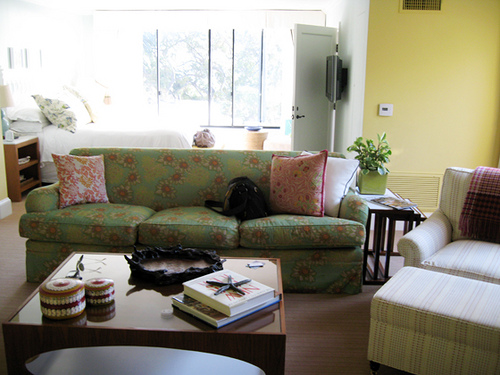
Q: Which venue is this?
A: This is a living room.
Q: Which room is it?
A: It is a living room.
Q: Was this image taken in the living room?
A: Yes, it was taken in the living room.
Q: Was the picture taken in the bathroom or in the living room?
A: It was taken at the living room.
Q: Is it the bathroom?
A: No, it is the living room.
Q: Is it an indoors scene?
A: Yes, it is indoors.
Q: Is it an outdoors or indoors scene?
A: It is indoors.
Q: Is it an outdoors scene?
A: No, it is indoors.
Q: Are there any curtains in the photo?
A: No, there are no curtains.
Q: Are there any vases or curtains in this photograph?
A: No, there are no curtains or vases.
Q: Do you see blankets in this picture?
A: Yes, there is a blanket.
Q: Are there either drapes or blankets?
A: Yes, there is a blanket.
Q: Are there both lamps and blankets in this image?
A: Yes, there are both a blanket and a lamp.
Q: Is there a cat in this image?
A: No, there are no cats.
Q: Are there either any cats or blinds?
A: No, there are no cats or blinds.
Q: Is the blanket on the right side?
A: Yes, the blanket is on the right of the image.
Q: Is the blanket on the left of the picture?
A: No, the blanket is on the right of the image.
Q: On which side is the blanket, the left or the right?
A: The blanket is on the right of the image.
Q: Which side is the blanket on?
A: The blanket is on the right of the image.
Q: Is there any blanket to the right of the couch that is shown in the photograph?
A: Yes, there is a blanket to the right of the couch.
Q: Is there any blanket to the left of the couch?
A: No, the blanket is to the right of the couch.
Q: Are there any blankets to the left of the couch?
A: No, the blanket is to the right of the couch.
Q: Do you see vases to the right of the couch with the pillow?
A: No, there is a blanket to the right of the couch.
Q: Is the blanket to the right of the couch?
A: Yes, the blanket is to the right of the couch.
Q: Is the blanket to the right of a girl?
A: No, the blanket is to the right of the couch.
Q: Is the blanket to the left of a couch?
A: No, the blanket is to the right of a couch.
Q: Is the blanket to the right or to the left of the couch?
A: The blanket is to the right of the couch.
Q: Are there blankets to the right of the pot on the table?
A: Yes, there is a blanket to the right of the pot.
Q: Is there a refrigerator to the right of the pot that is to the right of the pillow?
A: No, there is a blanket to the right of the pot.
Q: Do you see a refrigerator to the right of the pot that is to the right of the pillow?
A: No, there is a blanket to the right of the pot.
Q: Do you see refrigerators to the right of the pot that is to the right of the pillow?
A: No, there is a blanket to the right of the pot.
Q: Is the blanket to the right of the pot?
A: Yes, the blanket is to the right of the pot.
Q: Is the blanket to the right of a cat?
A: No, the blanket is to the right of the pot.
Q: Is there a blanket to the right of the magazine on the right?
A: Yes, there is a blanket to the right of the magazine.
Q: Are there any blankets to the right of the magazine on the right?
A: Yes, there is a blanket to the right of the magazine.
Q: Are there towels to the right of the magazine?
A: No, there is a blanket to the right of the magazine.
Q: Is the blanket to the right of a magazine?
A: Yes, the blanket is to the right of a magazine.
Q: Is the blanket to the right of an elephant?
A: No, the blanket is to the right of a magazine.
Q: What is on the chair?
A: The blanket is on the chair.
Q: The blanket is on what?
A: The blanket is on the chair.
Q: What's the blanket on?
A: The blanket is on the chair.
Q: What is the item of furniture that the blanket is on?
A: The piece of furniture is a chair.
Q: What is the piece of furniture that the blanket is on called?
A: The piece of furniture is a chair.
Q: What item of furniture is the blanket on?
A: The blanket is on the chair.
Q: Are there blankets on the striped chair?
A: Yes, there is a blanket on the chair.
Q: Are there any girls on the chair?
A: No, there is a blanket on the chair.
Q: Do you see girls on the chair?
A: No, there is a blanket on the chair.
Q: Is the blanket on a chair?
A: Yes, the blanket is on a chair.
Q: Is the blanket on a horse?
A: No, the blanket is on a chair.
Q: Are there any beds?
A: Yes, there is a bed.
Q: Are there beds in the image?
A: Yes, there is a bed.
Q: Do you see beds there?
A: Yes, there is a bed.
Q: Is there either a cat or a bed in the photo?
A: Yes, there is a bed.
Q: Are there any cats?
A: No, there are no cats.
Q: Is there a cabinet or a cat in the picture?
A: No, there are no cats or cabinets.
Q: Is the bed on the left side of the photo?
A: Yes, the bed is on the left of the image.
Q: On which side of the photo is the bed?
A: The bed is on the left of the image.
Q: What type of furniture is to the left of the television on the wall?
A: The piece of furniture is a bed.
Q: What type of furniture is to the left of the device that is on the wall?
A: The piece of furniture is a bed.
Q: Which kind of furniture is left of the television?
A: The piece of furniture is a bed.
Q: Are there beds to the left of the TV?
A: Yes, there is a bed to the left of the TV.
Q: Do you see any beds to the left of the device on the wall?
A: Yes, there is a bed to the left of the TV.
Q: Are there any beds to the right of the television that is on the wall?
A: No, the bed is to the left of the TV.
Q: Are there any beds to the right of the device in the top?
A: No, the bed is to the left of the TV.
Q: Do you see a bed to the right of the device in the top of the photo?
A: No, the bed is to the left of the TV.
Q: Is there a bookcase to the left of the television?
A: No, there is a bed to the left of the television.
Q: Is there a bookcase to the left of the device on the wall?
A: No, there is a bed to the left of the television.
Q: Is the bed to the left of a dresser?
A: No, the bed is to the left of a television.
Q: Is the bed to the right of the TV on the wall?
A: No, the bed is to the left of the TV.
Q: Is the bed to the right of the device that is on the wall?
A: No, the bed is to the left of the TV.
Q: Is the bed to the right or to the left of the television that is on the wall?
A: The bed is to the left of the TV.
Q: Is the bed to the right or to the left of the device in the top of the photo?
A: The bed is to the left of the TV.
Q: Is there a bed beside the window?
A: Yes, there is a bed beside the window.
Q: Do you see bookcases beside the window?
A: No, there is a bed beside the window.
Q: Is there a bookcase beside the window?
A: No, there is a bed beside the window.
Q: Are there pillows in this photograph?
A: Yes, there is a pillow.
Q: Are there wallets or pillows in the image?
A: Yes, there is a pillow.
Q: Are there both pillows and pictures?
A: No, there is a pillow but no pictures.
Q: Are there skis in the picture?
A: No, there are no skis.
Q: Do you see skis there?
A: No, there are no skis.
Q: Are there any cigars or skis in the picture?
A: No, there are no skis or cigars.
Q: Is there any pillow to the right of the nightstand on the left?
A: Yes, there is a pillow to the right of the nightstand.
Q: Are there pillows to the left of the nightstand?
A: No, the pillow is to the right of the nightstand.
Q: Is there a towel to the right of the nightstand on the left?
A: No, there is a pillow to the right of the nightstand.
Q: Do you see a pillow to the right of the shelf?
A: Yes, there is a pillow to the right of the shelf.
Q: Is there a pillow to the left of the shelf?
A: No, the pillow is to the right of the shelf.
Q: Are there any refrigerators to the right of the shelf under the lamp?
A: No, there is a pillow to the right of the shelf.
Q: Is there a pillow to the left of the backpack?
A: Yes, there is a pillow to the left of the backpack.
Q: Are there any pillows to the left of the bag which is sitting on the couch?
A: Yes, there is a pillow to the left of the backpack.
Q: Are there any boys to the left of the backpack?
A: No, there is a pillow to the left of the backpack.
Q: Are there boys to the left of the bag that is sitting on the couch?
A: No, there is a pillow to the left of the backpack.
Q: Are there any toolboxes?
A: No, there are no toolboxes.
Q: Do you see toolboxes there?
A: No, there are no toolboxes.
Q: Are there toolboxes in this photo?
A: No, there are no toolboxes.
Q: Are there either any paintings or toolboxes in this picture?
A: No, there are no toolboxes or paintings.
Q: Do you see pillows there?
A: Yes, there is a pillow.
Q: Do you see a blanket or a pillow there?
A: Yes, there is a pillow.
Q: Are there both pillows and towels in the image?
A: No, there is a pillow but no towels.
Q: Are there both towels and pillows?
A: No, there is a pillow but no towels.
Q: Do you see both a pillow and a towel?
A: No, there is a pillow but no towels.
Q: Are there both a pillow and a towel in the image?
A: No, there is a pillow but no towels.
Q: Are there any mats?
A: No, there are no mats.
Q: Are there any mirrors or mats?
A: No, there are no mats or mirrors.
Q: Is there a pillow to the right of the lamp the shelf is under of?
A: Yes, there is a pillow to the right of the lamp.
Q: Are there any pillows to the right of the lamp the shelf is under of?
A: Yes, there is a pillow to the right of the lamp.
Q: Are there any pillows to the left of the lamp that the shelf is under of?
A: No, the pillow is to the right of the lamp.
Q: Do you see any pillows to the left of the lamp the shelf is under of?
A: No, the pillow is to the right of the lamp.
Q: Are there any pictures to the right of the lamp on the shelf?
A: No, there is a pillow to the right of the lamp.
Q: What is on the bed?
A: The pillow is on the bed.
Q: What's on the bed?
A: The pillow is on the bed.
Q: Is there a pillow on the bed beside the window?
A: Yes, there is a pillow on the bed.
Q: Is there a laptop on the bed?
A: No, there is a pillow on the bed.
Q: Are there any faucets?
A: No, there are no faucets.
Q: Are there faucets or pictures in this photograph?
A: No, there are no faucets or pictures.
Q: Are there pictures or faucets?
A: No, there are no faucets or pictures.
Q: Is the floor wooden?
A: Yes, the floor is wooden.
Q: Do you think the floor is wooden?
A: Yes, the floor is wooden.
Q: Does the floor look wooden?
A: Yes, the floor is wooden.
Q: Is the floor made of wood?
A: Yes, the floor is made of wood.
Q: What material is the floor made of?
A: The floor is made of wood.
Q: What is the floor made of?
A: The floor is made of wood.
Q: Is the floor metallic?
A: No, the floor is wooden.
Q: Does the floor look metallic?
A: No, the floor is wooden.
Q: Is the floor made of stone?
A: No, the floor is made of wood.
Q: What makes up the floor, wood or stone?
A: The floor is made of wood.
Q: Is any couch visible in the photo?
A: Yes, there is a couch.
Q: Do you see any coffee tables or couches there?
A: Yes, there is a couch.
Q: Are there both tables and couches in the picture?
A: Yes, there are both a couch and a table.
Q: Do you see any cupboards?
A: No, there are no cupboards.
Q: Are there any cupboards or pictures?
A: No, there are no cupboards or pictures.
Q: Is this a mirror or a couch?
A: This is a couch.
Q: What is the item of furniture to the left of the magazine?
A: The piece of furniture is a couch.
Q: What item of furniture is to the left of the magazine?
A: The piece of furniture is a couch.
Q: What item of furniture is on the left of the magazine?
A: The piece of furniture is a couch.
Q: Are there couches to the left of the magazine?
A: Yes, there is a couch to the left of the magazine.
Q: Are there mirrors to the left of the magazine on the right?
A: No, there is a couch to the left of the magazine.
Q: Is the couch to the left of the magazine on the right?
A: Yes, the couch is to the left of the magazine.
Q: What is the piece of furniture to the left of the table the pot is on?
A: The piece of furniture is a couch.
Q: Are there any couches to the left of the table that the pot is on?
A: Yes, there is a couch to the left of the table.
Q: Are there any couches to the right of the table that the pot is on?
A: No, the couch is to the left of the table.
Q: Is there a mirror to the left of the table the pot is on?
A: No, there is a couch to the left of the table.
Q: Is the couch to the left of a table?
A: Yes, the couch is to the left of a table.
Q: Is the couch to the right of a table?
A: No, the couch is to the left of a table.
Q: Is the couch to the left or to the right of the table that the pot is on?
A: The couch is to the left of the table.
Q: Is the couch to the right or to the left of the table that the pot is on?
A: The couch is to the left of the table.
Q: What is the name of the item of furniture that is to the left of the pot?
A: The piece of furniture is a couch.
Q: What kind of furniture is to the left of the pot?
A: The piece of furniture is a couch.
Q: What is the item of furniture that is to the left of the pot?
A: The piece of furniture is a couch.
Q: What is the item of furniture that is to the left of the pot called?
A: The piece of furniture is a couch.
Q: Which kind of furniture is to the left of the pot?
A: The piece of furniture is a couch.